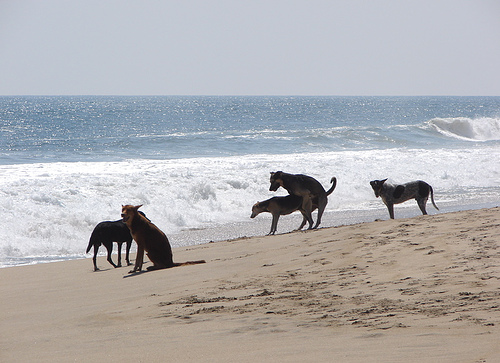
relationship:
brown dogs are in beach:
[85, 169, 440, 273] [0, 201, 498, 361]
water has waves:
[8, 87, 498, 268] [141, 112, 498, 146]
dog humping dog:
[263, 171, 337, 228] [250, 196, 316, 236]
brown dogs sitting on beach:
[120, 203, 206, 273] [7, 153, 496, 360]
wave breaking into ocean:
[417, 114, 499, 145] [5, 93, 498, 262]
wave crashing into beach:
[0, 139, 498, 261] [0, 206, 500, 363]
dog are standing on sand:
[263, 171, 337, 228] [6, 201, 496, 360]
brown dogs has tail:
[120, 203, 206, 273] [177, 246, 208, 277]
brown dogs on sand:
[120, 203, 206, 273] [6, 201, 496, 360]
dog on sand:
[82, 211, 142, 270] [6, 201, 496, 360]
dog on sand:
[263, 171, 337, 228] [6, 201, 496, 360]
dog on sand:
[249, 196, 318, 233] [6, 201, 496, 360]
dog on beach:
[368, 178, 440, 219] [10, 121, 493, 349]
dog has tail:
[366, 173, 452, 211] [425, 181, 445, 216]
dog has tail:
[263, 168, 310, 196] [322, 174, 342, 198]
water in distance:
[8, 87, 498, 268] [5, 74, 484, 142]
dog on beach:
[263, 171, 337, 228] [0, 201, 498, 361]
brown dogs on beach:
[120, 203, 206, 273] [0, 201, 498, 361]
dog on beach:
[263, 171, 337, 228] [0, 188, 479, 361]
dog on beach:
[368, 178, 440, 219] [0, 188, 479, 361]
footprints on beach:
[145, 204, 492, 356] [0, 201, 498, 361]